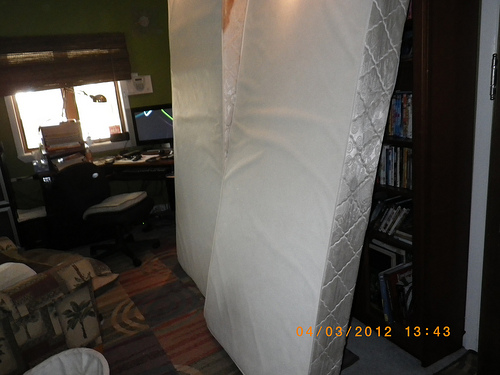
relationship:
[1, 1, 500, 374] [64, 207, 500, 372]
room has a floor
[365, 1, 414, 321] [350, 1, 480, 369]
books on shelving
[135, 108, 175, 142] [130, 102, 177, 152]
screen saver on computer monitor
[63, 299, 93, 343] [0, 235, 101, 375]
design on side of chair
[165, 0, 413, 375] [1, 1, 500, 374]
two mattresses in room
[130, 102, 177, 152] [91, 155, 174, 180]
computer screen on desk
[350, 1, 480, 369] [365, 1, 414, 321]
shelf with books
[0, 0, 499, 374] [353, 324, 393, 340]
picture was taken in 2012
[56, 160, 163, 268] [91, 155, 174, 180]
chair in front of desk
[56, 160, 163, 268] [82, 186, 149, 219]
chair has cushion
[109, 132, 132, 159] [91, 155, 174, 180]
lamp over desk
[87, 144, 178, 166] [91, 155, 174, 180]
stuff on desk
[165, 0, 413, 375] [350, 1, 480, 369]
two mattresses are leaning on shelving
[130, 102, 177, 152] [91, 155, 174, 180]
computer monitor on desk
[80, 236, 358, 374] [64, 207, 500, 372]
rug on floor